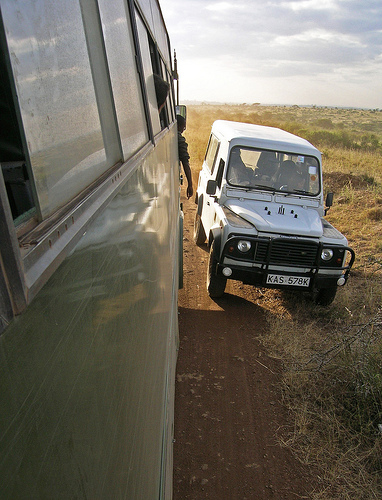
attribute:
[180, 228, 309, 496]
road — dirt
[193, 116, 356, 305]
truck — jeep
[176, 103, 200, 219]
men — one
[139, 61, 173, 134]
men — another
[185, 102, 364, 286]
truck — white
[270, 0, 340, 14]
white cloud — small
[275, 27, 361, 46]
white cloud — puffy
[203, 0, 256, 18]
white cloud — perfect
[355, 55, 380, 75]
white cloud — little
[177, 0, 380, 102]
sky — overhead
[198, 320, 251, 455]
road — dry, dusty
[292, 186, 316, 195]
wiper — double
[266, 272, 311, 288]
license — plate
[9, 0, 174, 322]
windows — are dirty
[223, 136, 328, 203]
windows — are dirty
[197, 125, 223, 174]
windows — are dirty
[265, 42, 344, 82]
sky — overcast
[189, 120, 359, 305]
vehicle — white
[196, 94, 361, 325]
truck — white 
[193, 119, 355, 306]
jeep — nice, new, is white, nearby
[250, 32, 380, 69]
cloud — thick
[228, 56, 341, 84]
cloud — thick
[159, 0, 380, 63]
cloud — thick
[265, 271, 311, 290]
white plate — is white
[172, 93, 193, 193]
man — tall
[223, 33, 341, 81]
clouds — several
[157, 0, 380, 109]
sky — white, blue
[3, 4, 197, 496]
bus — passenger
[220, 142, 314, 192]
people — three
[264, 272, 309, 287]
license — black and white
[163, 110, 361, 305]
jeep — nearby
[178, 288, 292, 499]
road — dirt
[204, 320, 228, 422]
road — dusty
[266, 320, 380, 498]
grass — dead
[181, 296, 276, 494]
road — brown, rocky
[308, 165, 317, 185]
stickers — white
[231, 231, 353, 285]
cow catcher — is black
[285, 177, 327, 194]
man — lone